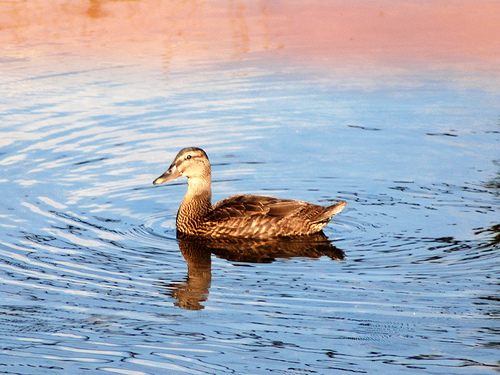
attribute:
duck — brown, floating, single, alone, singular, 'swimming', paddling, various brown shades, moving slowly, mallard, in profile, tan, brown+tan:
[148, 144, 350, 246]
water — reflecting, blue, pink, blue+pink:
[3, 1, 499, 372]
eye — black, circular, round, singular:
[186, 153, 193, 160]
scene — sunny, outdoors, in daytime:
[2, 1, 499, 373]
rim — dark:
[184, 152, 193, 162]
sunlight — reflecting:
[2, 49, 342, 375]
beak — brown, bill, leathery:
[150, 162, 182, 190]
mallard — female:
[150, 142, 353, 244]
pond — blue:
[2, 67, 498, 375]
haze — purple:
[2, 46, 499, 106]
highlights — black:
[173, 140, 213, 181]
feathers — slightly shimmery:
[175, 193, 326, 239]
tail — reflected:
[318, 197, 349, 229]